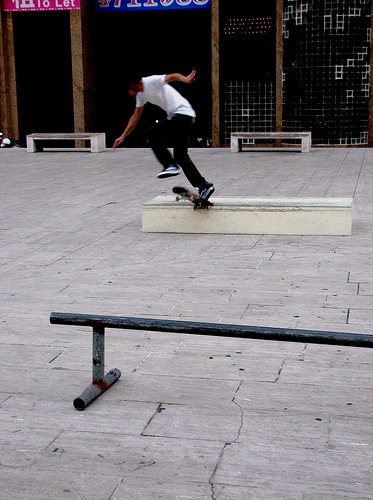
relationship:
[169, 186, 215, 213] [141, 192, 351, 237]
skateboard used to grind ledge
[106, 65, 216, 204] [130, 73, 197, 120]
young man wearing shirt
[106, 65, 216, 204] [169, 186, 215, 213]
young man on skateboard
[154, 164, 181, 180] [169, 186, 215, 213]
foot off skateboard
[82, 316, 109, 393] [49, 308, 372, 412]
paint on rail